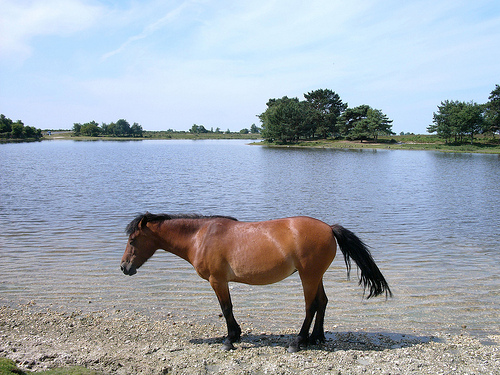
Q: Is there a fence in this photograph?
A: No, there are no fences.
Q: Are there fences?
A: No, there are no fences.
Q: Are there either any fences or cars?
A: No, there are no fences or cars.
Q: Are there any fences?
A: No, there are no fences.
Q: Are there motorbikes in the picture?
A: No, there are no motorbikes.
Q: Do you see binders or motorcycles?
A: No, there are no motorcycles or binders.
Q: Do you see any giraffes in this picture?
A: No, there are no giraffes.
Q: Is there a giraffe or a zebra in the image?
A: No, there are no giraffes or zebras.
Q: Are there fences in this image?
A: No, there are no fences.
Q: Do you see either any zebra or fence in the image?
A: No, there are no fences or zebras.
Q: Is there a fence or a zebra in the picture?
A: No, there are no fences or zebras.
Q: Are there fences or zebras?
A: No, there are no fences or zebras.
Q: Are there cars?
A: No, there are no cars.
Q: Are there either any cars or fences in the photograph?
A: No, there are no cars or fences.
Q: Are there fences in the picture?
A: No, there are no fences.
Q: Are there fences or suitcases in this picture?
A: No, there are no fences or suitcases.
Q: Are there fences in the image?
A: No, there are no fences.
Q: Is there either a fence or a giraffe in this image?
A: No, there are no fences or giraffes.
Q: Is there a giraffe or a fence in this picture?
A: No, there are no fences or giraffes.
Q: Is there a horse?
A: Yes, there is a horse.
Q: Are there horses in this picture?
A: Yes, there is a horse.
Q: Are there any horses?
A: Yes, there is a horse.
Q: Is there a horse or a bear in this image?
A: Yes, there is a horse.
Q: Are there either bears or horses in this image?
A: Yes, there is a horse.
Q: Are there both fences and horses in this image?
A: No, there is a horse but no fences.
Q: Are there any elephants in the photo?
A: No, there are no elephants.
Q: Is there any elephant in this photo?
A: No, there are no elephants.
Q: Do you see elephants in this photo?
A: No, there are no elephants.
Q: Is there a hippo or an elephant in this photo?
A: No, there are no elephants or hippoes.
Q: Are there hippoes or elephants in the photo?
A: No, there are no elephants or hippoes.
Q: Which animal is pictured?
A: The animal is a horse.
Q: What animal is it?
A: The animal is a horse.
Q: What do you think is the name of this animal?
A: This is a horse.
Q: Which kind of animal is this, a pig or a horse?
A: This is a horse.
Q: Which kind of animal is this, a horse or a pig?
A: This is a horse.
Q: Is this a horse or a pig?
A: This is a horse.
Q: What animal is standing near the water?
A: The horse is standing near the water.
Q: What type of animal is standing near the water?
A: The animal is a horse.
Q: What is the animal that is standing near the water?
A: The animal is a horse.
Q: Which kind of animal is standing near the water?
A: The animal is a horse.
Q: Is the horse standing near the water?
A: Yes, the horse is standing near the water.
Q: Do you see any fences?
A: No, there are no fences.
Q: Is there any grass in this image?
A: Yes, there is grass.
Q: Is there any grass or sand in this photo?
A: Yes, there is grass.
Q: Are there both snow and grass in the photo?
A: No, there is grass but no snow.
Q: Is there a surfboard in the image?
A: No, there are no surfboards.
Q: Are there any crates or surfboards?
A: No, there are no surfboards or crates.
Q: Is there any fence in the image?
A: No, there are no fences.